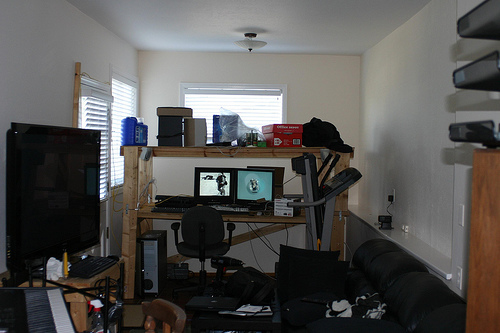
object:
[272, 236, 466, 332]
couch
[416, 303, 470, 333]
cushion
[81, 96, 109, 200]
blinds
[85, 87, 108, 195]
set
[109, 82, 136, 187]
set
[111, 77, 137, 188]
blinds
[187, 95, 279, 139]
set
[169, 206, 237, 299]
chair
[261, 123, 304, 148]
box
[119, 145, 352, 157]
shelf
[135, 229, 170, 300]
tower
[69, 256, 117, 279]
keyboard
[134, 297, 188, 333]
chair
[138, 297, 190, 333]
top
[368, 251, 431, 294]
cushion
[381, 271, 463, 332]
cushion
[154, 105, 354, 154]
clutter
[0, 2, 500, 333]
room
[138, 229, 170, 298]
clutter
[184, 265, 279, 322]
clutter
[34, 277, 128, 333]
clutter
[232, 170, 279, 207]
monitors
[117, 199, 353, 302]
desk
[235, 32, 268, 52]
light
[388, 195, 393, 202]
plug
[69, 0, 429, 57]
ceiling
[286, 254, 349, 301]
pillows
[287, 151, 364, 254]
exercise machine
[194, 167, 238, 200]
monitor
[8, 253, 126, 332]
table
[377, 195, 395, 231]
an apparatus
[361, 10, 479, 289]
wall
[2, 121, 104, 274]
television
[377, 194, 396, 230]
wall charger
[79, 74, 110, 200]
window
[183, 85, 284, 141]
window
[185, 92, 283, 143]
blinds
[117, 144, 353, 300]
cabinet